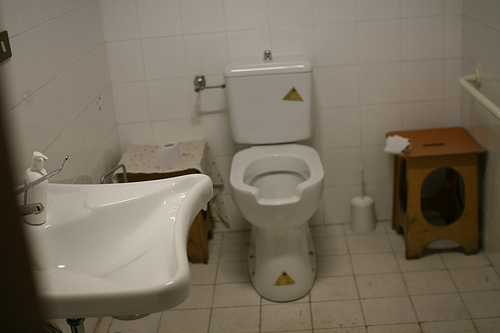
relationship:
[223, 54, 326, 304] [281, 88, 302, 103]
toilet has a sticker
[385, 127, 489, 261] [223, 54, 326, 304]
stool next to toilet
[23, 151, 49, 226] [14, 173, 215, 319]
dispenser on sink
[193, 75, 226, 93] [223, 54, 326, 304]
pipe connects to toilet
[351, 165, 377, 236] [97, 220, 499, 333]
toilet cleaner on floor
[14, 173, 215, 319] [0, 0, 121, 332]
sink attached to wall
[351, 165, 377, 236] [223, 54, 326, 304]
cleaner for toilet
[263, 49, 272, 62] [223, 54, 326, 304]
button on toilet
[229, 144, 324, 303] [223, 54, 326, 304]
base of toilet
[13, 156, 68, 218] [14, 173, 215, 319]
faucet on sink